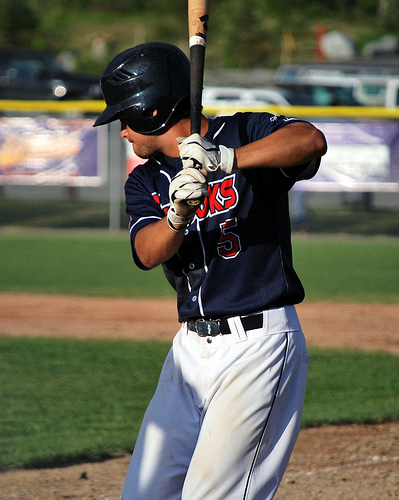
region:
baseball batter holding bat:
[87, 0, 332, 498]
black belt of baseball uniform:
[179, 313, 264, 333]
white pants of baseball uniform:
[119, 307, 309, 499]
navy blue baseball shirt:
[122, 112, 322, 316]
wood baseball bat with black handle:
[184, 0, 208, 133]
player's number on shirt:
[210, 218, 248, 262]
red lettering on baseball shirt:
[152, 177, 239, 220]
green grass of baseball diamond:
[0, 227, 397, 465]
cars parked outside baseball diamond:
[0, 43, 398, 110]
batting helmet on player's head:
[92, 37, 190, 133]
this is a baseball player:
[85, 0, 316, 497]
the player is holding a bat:
[137, 2, 250, 223]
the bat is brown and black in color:
[182, 0, 228, 139]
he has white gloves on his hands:
[165, 131, 222, 217]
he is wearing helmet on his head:
[95, 45, 177, 127]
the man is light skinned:
[278, 132, 300, 151]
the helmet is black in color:
[96, 47, 179, 122]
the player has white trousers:
[157, 349, 287, 494]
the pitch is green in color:
[2, 342, 113, 452]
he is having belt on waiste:
[195, 323, 227, 330]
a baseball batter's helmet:
[92, 39, 189, 132]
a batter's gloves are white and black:
[174, 130, 230, 173]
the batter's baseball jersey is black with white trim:
[121, 110, 315, 317]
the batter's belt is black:
[186, 310, 258, 333]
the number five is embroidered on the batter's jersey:
[214, 214, 236, 254]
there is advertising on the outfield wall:
[0, 116, 109, 188]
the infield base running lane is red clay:
[1, 292, 398, 348]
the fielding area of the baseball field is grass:
[0, 335, 397, 469]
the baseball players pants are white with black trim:
[121, 304, 307, 498]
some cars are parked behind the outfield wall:
[273, 64, 398, 106]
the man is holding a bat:
[90, 26, 314, 256]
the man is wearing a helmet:
[95, 40, 211, 179]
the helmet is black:
[95, 49, 204, 153]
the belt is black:
[164, 314, 236, 344]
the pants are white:
[121, 299, 251, 495]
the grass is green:
[10, 371, 105, 453]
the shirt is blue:
[119, 155, 258, 329]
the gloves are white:
[154, 37, 249, 193]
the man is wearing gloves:
[147, 126, 250, 220]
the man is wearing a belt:
[73, 59, 303, 370]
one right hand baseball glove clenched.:
[167, 169, 205, 222]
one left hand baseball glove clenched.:
[180, 136, 235, 174]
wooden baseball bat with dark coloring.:
[186, 0, 204, 140]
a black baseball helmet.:
[95, 42, 190, 123]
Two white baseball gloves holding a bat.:
[160, 137, 238, 216]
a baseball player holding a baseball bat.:
[110, 0, 320, 339]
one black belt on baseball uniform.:
[168, 312, 300, 334]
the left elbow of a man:
[235, 105, 337, 184]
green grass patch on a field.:
[16, 343, 119, 447]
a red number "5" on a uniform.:
[212, 216, 249, 265]